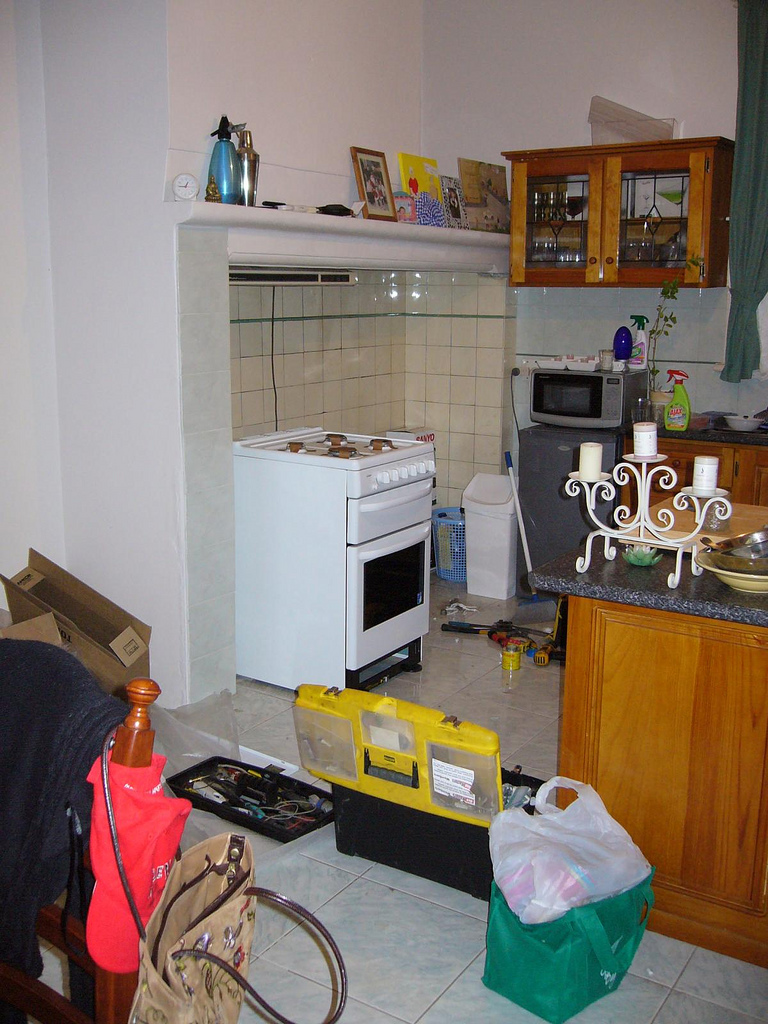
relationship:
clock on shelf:
[164, 162, 200, 206] [164, 162, 390, 254]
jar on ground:
[493, 640, 528, 677] [464, 670, 544, 696]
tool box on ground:
[282, 683, 555, 926] [282, 851, 478, 926]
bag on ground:
[477, 878, 649, 1006] [477, 962, 730, 1006]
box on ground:
[6, 534, 156, 707] [368, 872, 431, 960]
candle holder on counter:
[554, 417, 738, 595] [691, 406, 761, 446]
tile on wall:
[59, 277, 142, 366] [65, 228, 135, 400]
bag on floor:
[479, 773, 656, 1017] [319, 862, 393, 949]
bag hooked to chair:
[96, 705, 355, 1017] [6, 695, 65, 904]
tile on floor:
[306, 325, 372, 365] [129, 705, 757, 1017]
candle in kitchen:
[565, 439, 615, 480] [1, 1, 763, 1022]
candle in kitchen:
[561, 452, 611, 501] [1, 1, 755, 905]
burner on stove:
[326, 446, 357, 459] [242, 445, 398, 673]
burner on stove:
[320, 446, 361, 456] [227, 409, 444, 693]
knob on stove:
[406, 460, 422, 477] [227, 409, 444, 693]